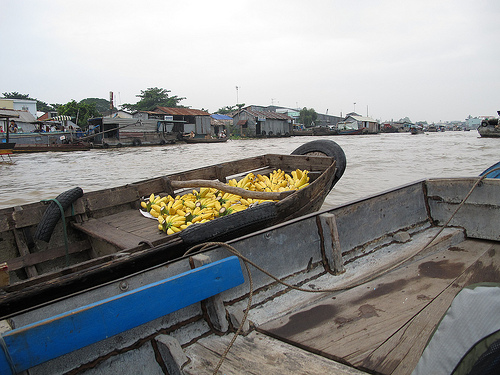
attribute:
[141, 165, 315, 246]
bananas — yellow, bunched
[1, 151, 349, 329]
boat — in motion, woodeny, brown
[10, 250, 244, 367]
plank — blue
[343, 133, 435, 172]
water — calm, murky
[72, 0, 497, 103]
sky — cloudy, hazy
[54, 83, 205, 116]
trees — growing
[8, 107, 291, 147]
houses — on the side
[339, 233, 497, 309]
deck — grey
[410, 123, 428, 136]
boat — distant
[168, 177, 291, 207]
pole — wooden